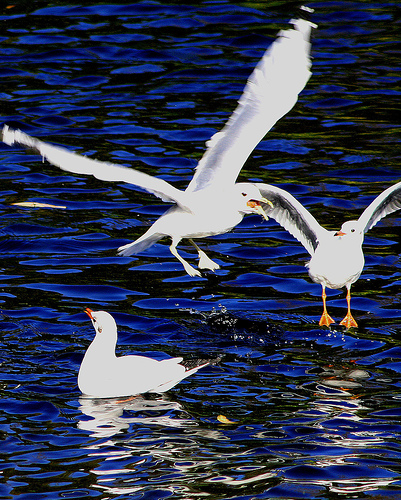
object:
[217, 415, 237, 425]
leaf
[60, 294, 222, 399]
seagull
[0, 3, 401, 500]
water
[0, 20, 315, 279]
bird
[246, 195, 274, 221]
mouth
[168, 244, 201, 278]
leg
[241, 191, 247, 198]
eye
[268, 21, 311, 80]
feather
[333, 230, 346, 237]
beak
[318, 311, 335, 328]
feet